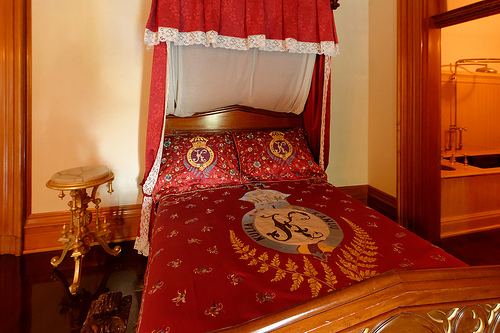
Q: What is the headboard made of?
A: Wood.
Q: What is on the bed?
A: Blankets and pillows.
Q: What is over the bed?
A: A window.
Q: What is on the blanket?
A: A picture.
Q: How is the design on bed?
A: Gold.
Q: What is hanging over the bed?
A: Red and white fabric.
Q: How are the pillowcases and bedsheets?
A: Matching.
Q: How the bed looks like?
A: Good.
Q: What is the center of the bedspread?
A: Family crest.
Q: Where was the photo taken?
A: Bedroom.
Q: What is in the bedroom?
A: Bathroom.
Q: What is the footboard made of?
A: Wood.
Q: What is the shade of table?
A: Gold.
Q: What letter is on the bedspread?
A: K.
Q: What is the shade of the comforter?
A: Red.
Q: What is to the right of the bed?
A: Bathroom.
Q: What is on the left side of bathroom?
A: Shower.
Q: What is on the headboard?
A: Two pillows.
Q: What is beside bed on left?
A: Stand.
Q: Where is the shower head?
A: Bathroom.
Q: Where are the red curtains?
A: Top of bed.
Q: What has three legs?
A: Table.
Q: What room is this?
A: Bedroom.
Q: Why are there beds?
A: For sleeping.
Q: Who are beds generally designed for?
A: People.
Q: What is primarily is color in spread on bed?
A: Red.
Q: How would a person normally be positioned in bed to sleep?
A: Laying down.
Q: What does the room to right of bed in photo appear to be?
A: Bathroom.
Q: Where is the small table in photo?
A: To left of bed.